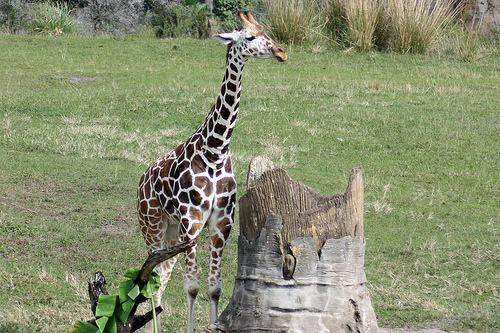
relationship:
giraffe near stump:
[136, 11, 288, 333] [236, 155, 382, 319]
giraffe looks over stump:
[136, 11, 288, 333] [201, 151, 378, 333]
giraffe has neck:
[136, 11, 288, 333] [193, 54, 244, 151]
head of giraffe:
[206, 7, 291, 64] [136, 11, 288, 333]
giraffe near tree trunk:
[136, 11, 288, 333] [219, 148, 409, 326]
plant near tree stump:
[69, 242, 183, 325] [241, 132, 395, 331]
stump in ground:
[251, 134, 355, 276] [0, 32, 499, 331]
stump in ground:
[201, 151, 378, 333] [0, 32, 499, 331]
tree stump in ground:
[85, 259, 162, 331] [0, 32, 499, 331]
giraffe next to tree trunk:
[103, 10, 288, 331] [202, 156, 378, 333]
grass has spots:
[1, 29, 495, 331] [184, 71, 413, 102]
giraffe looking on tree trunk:
[136, 11, 288, 333] [202, 156, 378, 333]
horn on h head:
[232, 4, 257, 29] [211, 12, 287, 76]